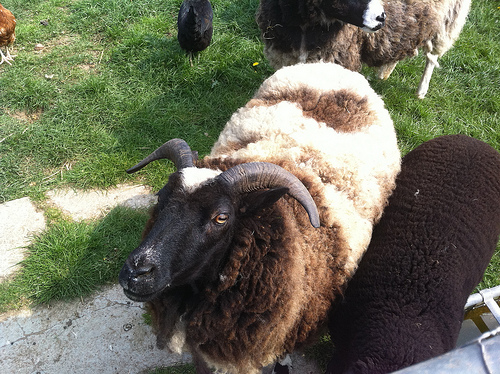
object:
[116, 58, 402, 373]
sheep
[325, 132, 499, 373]
sheep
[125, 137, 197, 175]
horns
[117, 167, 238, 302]
face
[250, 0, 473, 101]
sheep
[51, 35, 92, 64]
grass